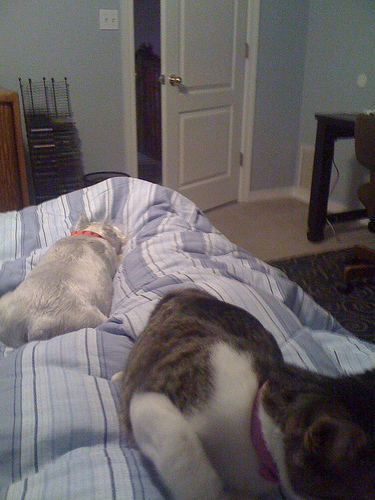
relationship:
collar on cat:
[244, 375, 283, 477] [144, 255, 370, 468]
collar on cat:
[70, 223, 106, 239] [0, 213, 128, 349]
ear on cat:
[75, 213, 87, 232] [22, 186, 140, 346]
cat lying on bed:
[0, 213, 128, 349] [2, 175, 368, 495]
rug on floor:
[262, 242, 375, 342] [234, 196, 295, 238]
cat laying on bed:
[0, 213, 128, 349] [2, 175, 368, 495]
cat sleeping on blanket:
[0, 213, 128, 349] [0, 176, 371, 499]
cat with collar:
[0, 213, 128, 349] [67, 228, 106, 239]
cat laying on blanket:
[120, 284, 375, 500] [0, 176, 371, 499]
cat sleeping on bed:
[148, 275, 374, 498] [20, 187, 362, 490]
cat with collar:
[120, 284, 375, 500] [249, 378, 279, 485]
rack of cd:
[17, 75, 85, 198] [24, 112, 54, 124]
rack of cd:
[17, 75, 85, 198] [28, 126, 58, 136]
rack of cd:
[17, 75, 85, 198] [25, 129, 58, 139]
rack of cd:
[17, 75, 85, 198] [25, 137, 66, 151]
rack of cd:
[17, 75, 85, 198] [53, 119, 77, 129]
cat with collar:
[120, 284, 375, 500] [248, 369, 279, 484]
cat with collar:
[5, 201, 128, 342] [70, 226, 105, 241]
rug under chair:
[272, 212, 372, 342] [308, 109, 360, 237]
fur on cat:
[62, 281, 76, 294] [8, 203, 134, 332]